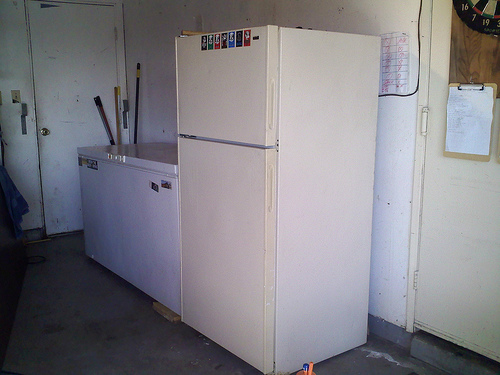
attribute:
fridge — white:
[151, 17, 393, 372]